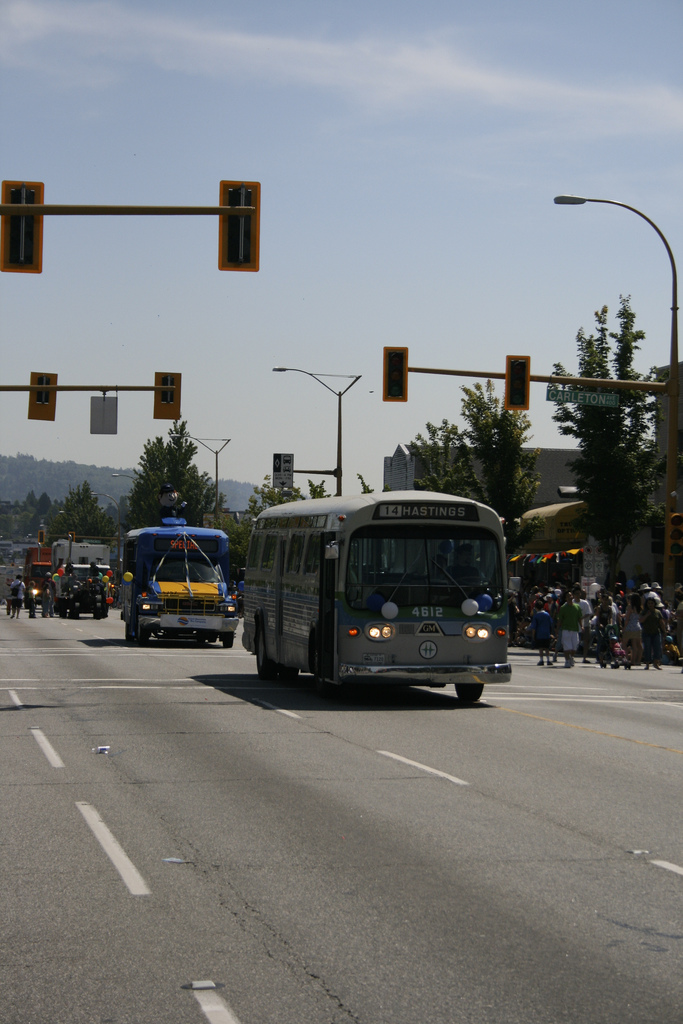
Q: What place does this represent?
A: It represents the road.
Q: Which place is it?
A: It is a road.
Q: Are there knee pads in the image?
A: No, there are no knee pads.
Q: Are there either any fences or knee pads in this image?
A: No, there are no knee pads or fences.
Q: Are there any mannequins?
A: No, there are no mannequins.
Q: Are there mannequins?
A: No, there are no mannequins.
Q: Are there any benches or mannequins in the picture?
A: No, there are no mannequins or benches.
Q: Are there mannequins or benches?
A: No, there are no mannequins or benches.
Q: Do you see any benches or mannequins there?
A: No, there are no mannequins or benches.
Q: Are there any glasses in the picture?
A: No, there are no glasses.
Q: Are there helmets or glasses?
A: No, there are no glasses or helmets.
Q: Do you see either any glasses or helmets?
A: No, there are no glasses or helmets.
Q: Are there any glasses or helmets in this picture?
A: No, there are no glasses or helmets.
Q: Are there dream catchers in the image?
A: No, there are no dream catchers.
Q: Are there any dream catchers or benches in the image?
A: No, there are no dream catchers or benches.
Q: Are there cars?
A: No, there are no cars.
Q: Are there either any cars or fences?
A: No, there are no cars or fences.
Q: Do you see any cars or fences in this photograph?
A: No, there are no cars or fences.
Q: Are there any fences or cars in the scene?
A: No, there are no cars or fences.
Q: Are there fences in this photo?
A: No, there are no fences.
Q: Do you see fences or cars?
A: No, there are no fences or cars.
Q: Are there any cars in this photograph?
A: No, there are no cars.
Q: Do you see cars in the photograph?
A: No, there are no cars.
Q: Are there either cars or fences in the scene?
A: No, there are no cars or fences.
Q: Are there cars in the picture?
A: No, there are no cars.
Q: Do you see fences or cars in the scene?
A: No, there are no cars or fences.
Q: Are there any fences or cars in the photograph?
A: No, there are no cars or fences.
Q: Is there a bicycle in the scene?
A: No, there are no bicycles.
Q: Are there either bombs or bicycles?
A: No, there are no bicycles or bombs.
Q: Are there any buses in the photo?
A: Yes, there is a bus.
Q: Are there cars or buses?
A: Yes, there is a bus.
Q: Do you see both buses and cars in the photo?
A: No, there is a bus but no cars.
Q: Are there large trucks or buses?
A: Yes, there is a large bus.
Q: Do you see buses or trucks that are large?
A: Yes, the bus is large.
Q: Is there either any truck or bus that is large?
A: Yes, the bus is large.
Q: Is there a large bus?
A: Yes, there is a large bus.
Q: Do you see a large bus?
A: Yes, there is a large bus.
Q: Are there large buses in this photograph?
A: Yes, there is a large bus.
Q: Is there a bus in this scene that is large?
A: Yes, there is a bus that is large.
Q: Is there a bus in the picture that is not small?
A: Yes, there is a large bus.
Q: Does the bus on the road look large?
A: Yes, the bus is large.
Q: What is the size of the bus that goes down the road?
A: The bus is large.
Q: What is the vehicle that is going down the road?
A: The vehicle is a bus.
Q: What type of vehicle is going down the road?
A: The vehicle is a bus.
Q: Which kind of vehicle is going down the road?
A: The vehicle is a bus.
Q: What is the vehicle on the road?
A: The vehicle is a bus.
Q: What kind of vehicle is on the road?
A: The vehicle is a bus.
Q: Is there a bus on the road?
A: Yes, there is a bus on the road.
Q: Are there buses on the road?
A: Yes, there is a bus on the road.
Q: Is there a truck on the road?
A: No, there is a bus on the road.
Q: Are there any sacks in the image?
A: No, there are no sacks.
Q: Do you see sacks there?
A: No, there are no sacks.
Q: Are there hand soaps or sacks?
A: No, there are no sacks or hand soaps.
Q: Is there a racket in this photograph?
A: No, there are no rackets.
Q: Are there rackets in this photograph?
A: No, there are no rackets.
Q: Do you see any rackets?
A: No, there are no rackets.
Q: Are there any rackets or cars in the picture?
A: No, there are no rackets or cars.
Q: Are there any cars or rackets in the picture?
A: No, there are no rackets or cars.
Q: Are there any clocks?
A: No, there are no clocks.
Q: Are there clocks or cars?
A: No, there are no clocks or cars.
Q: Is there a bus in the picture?
A: Yes, there is a bus.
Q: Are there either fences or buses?
A: Yes, there is a bus.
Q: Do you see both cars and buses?
A: No, there is a bus but no cars.